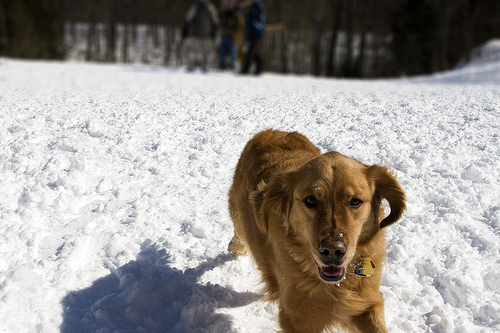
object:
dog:
[227, 126, 407, 331]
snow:
[0, 57, 500, 331]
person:
[180, 0, 224, 75]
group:
[174, 1, 271, 78]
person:
[212, 2, 243, 73]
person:
[239, 1, 269, 77]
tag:
[355, 254, 379, 278]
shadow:
[59, 236, 264, 331]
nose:
[315, 228, 349, 259]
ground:
[0, 50, 500, 331]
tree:
[0, 1, 500, 77]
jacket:
[242, 2, 268, 44]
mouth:
[312, 252, 353, 287]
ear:
[246, 171, 295, 237]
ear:
[367, 160, 408, 228]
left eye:
[350, 195, 365, 211]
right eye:
[301, 194, 319, 210]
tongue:
[319, 266, 344, 280]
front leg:
[351, 303, 389, 331]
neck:
[279, 195, 380, 288]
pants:
[240, 38, 265, 75]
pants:
[215, 33, 238, 71]